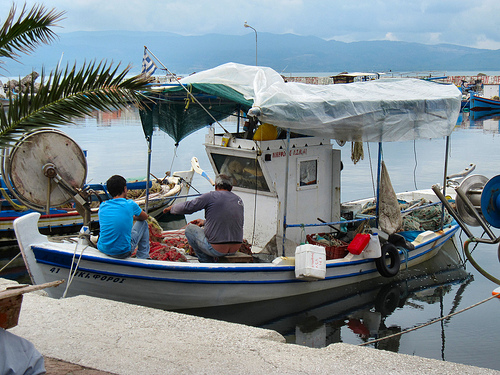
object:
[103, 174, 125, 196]
hair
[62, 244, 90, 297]
rope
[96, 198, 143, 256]
shirt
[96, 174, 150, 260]
man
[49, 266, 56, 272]
number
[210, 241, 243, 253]
skin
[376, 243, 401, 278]
tire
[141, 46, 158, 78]
flag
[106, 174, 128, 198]
head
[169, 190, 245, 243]
shirt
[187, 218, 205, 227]
hand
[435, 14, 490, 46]
cloud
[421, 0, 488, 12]
cloud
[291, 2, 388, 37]
cloud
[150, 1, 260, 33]
cloud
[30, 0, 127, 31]
cloud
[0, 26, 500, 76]
mountain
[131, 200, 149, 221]
arm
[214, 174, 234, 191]
head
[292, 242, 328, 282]
can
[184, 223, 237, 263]
jeans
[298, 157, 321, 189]
window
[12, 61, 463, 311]
boat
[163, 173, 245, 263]
man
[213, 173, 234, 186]
cap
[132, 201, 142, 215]
sleeve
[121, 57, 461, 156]
canopy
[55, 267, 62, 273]
number